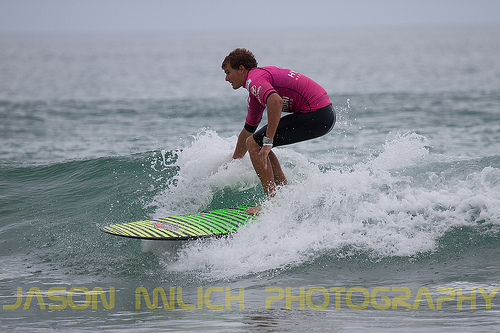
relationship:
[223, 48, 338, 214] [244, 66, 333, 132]
man wearing a shirt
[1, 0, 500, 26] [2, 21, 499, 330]
sky above water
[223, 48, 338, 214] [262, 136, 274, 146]
man wearing watch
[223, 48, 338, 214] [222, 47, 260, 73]
man has hair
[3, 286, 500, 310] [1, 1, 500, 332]
watermark on picture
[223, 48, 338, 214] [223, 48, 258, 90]
man has a head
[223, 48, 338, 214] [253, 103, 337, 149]
man wearing swimming shorts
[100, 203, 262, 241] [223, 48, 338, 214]
surfboard under man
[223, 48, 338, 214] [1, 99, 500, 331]
man riding wave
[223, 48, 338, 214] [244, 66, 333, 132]
man wearing shirt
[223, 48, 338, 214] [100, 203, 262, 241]
man on surfboard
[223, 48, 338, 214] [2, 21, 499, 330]
man on water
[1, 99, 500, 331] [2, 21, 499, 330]
wave in water